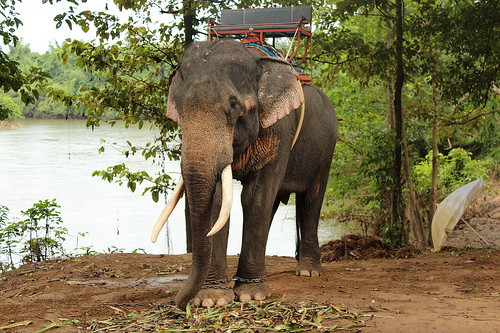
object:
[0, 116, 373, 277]
beach water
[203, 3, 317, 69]
chair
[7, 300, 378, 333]
leaves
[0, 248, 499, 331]
floor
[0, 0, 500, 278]
plants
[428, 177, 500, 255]
umbrella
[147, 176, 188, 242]
tusk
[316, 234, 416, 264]
dirt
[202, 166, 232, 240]
tusk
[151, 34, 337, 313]
elephant